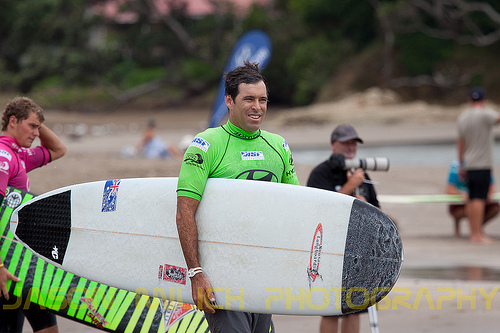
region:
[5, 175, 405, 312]
a white surfboard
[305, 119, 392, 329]
a photographer in the back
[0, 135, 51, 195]
a pink shirt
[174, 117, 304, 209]
a green shirt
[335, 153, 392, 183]
a long lens camera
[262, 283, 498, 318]
the word PHOTOGRPAHY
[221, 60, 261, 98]
the dark hair on the man's head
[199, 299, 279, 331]
the man's gray shorts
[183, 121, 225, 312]
the arm carrying the surfboard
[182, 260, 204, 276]
the white object on the man's wrist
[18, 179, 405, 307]
white surfboard with black on the top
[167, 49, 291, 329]
man with green shirt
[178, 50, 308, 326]
man wearing gray shorts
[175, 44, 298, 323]
man wearing white watch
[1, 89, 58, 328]
man wearing pink shirt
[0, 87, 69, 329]
man wearing black shorts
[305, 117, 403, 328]
man wearing black shirt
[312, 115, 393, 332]
man holding a camera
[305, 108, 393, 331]
man wearing brown baseball cap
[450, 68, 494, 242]
man wearing tan shirt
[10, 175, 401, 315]
black and white surf broad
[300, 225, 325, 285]
red symbol on broad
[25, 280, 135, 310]
green and black surf broad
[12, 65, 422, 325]
man carrying a surf broad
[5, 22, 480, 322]
people on a beach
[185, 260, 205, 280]
watch on right arm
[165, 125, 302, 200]
green shirt on surfer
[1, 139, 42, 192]
pink shirt of a surfer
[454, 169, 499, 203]
black shorts on a man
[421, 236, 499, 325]
sand on a beach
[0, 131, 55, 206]
THE MAN IS WEARING A SHIRT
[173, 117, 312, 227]
THE SHIRT IS GREEN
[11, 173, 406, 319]
THE MAN IS CARRYING A SURF BOARD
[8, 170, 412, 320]
THE SURF BOARD IS WHITE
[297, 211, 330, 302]
THE SURF BOARD HAS A LOGO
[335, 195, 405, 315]
THE END OF THE SURF BOARD IS GREY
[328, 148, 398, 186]
THE MAN IS HOLDING A CAMERA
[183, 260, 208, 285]
THE MAN IS WEARING A BRACELET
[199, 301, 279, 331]
THE MAN IS WEARING GREY SHORTS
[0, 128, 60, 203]
THE MAN IS WEARING A PINK SHIRT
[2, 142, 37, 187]
a pink body shirt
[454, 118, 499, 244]
a person standing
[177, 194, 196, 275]
the mans arm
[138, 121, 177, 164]
a person sitting on the sand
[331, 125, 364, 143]
a grey hat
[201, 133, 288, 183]
man wearing a green shirt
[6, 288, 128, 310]
a green striped surfboard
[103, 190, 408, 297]
man is holding a surfboard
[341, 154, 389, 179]
a camera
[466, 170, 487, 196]
black shorts